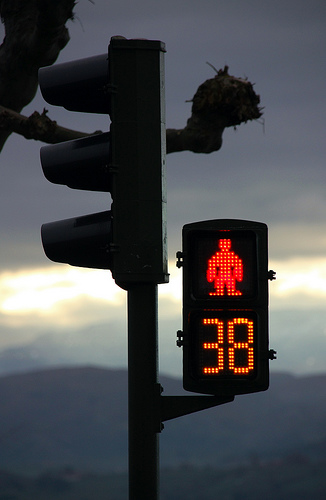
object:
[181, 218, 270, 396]
light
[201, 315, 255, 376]
number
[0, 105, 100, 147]
stick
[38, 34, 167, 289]
light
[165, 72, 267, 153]
stick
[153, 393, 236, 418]
pole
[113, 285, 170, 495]
pole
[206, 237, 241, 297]
man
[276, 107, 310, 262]
sky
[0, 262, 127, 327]
clouds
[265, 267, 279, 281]
knob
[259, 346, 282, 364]
knob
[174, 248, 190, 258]
knob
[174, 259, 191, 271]
knob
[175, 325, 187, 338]
knob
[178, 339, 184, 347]
knob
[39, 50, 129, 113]
top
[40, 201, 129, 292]
bottom